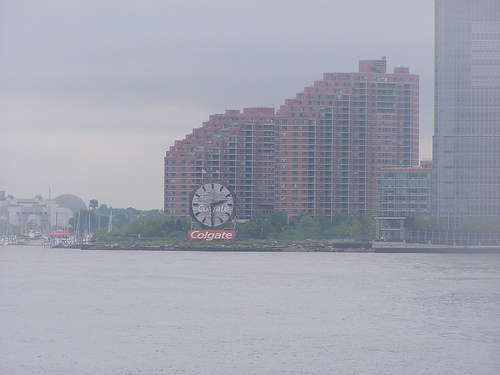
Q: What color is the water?
A: Grey.